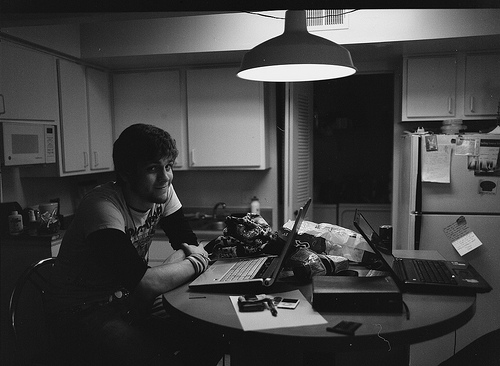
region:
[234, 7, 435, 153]
lighting fixture is hanging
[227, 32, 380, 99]
The light is bright.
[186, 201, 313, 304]
This is a laptop computer.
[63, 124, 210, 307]
The man is working.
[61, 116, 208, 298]
The man is smiling.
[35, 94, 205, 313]
The man sitting at the table.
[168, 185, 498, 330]
Three computers are on the table being used.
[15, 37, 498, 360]
He is in a kitchen.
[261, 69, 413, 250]
The door is open.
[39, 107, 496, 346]
He is sitting at a kitchen table.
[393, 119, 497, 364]
The refrigerator is closed.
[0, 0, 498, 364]
a black and white indoor image of a kitchen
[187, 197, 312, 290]
a laptop on the kitchen table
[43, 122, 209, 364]
a man sitting at the kitchen table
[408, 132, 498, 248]
the refrigerator aginst the wall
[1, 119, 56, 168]
a microwave oven above the kitchen counter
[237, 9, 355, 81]
a ceiling lamp above the kitchen table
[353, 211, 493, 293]
a black lap top across from the man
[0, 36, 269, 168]
white formica kitchen cabinets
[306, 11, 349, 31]
air conditioning vent above the door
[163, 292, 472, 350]
a dark round kitchen table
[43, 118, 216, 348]
Man sitting and smiling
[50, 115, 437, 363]
Man sitting at a table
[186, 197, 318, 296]
Open laptop on a table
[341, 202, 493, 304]
Open laptop on a table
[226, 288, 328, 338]
Paper with electronics on top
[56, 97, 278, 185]
White kitchen cabinets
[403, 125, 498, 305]
White refrigerator in the kitchen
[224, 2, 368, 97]
Overhead light turned on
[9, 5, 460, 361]
Black and white coloring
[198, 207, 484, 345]
Table covered in clutter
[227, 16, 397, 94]
bright over head light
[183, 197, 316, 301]
lap top with silver keyboard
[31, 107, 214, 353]
smiling boy in a t-shirt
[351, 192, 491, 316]
black lap top on the table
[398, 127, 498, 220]
freezer door with papers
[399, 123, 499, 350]
refrigerator with magnets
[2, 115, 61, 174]
white under the cabinet microwave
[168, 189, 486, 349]
round kitchen table with two lap tops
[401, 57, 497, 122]
white cabinets over the refrigerator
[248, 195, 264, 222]
white water bottle with lid